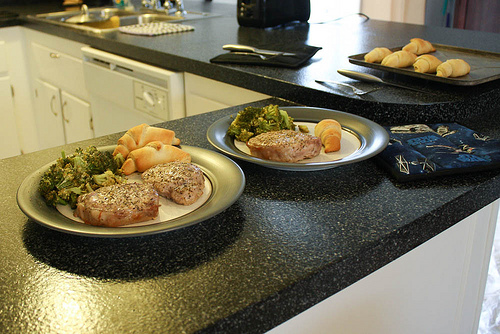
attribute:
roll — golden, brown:
[114, 140, 195, 175]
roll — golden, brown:
[103, 120, 180, 160]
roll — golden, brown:
[308, 115, 343, 154]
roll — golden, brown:
[434, 52, 471, 77]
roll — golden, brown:
[407, 52, 444, 74]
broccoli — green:
[37, 142, 126, 207]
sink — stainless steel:
[24, 6, 188, 37]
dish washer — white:
[83, 60, 183, 125]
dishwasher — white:
[80, 48, 185, 135]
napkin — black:
[217, 55, 293, 70]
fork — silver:
[312, 75, 384, 101]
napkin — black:
[209, 37, 320, 69]